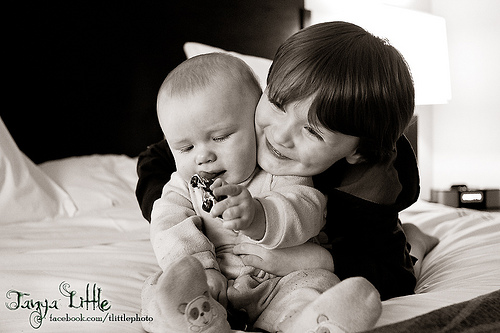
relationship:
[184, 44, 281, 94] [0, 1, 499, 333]
pillow on bed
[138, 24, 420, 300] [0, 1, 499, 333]
kid on bed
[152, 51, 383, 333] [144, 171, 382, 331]
baby has pajamas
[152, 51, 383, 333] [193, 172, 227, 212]
baby holding car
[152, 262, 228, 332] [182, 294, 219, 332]
foot has teddy bear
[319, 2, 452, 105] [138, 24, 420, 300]
lamp behind child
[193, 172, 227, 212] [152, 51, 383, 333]
car held by boy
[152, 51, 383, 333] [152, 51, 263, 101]
boy has hair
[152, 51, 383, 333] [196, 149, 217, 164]
boy has nose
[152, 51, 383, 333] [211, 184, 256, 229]
boy has hand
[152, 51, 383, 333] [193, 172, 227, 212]
boy has toy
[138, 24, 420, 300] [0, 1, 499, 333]
child on bed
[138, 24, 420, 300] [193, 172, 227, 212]
child has toy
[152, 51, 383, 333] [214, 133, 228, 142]
boy has eye